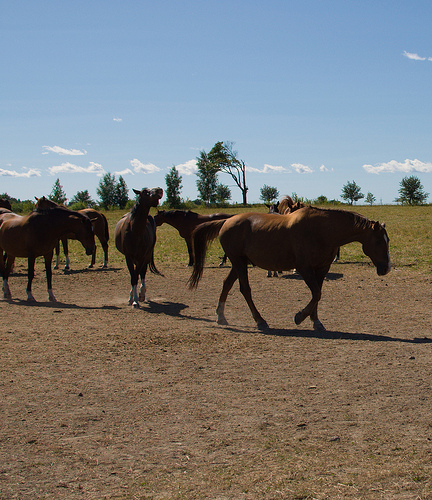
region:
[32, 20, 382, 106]
patch of clear blue sky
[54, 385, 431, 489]
smooth grund for walking on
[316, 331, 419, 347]
horse's shadow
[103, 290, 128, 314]
dust kicked up by horse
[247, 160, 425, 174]
row of white, thin clouds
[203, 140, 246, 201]
tree with no leaves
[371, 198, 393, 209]
fence for boundaries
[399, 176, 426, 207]
short tree with leaves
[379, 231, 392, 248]
white strip of fur on horse's head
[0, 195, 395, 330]
cluster of horses roaming the grounds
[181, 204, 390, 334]
brown horse on a field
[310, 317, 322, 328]
hoove of a horse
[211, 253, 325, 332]
four legs of a horse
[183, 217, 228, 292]
brown tail of a horse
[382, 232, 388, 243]
white spot on a horses head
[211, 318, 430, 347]
horse shadow on a ground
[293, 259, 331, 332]
front legs of a horse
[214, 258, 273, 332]
back legs of a horse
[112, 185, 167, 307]
brown horse with its head in the air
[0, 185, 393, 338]
brown horses on a dirt ground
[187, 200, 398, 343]
brown horse walking on dirt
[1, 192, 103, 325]
brown horse walking on dirt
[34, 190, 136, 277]
brown horse walking on dirt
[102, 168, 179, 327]
brown horse walking on dirt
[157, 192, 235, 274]
brown horse walking on dirt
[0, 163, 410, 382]
brown horses walking on dirt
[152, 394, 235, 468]
area of loose dirt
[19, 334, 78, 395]
area of loose dirt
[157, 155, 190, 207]
tall green leafy tree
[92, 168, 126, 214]
tall green leafy tree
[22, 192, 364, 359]
horses are in field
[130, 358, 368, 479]
ground is dry and brown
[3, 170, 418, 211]
few trees in distance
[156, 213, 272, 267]
horse has brown tail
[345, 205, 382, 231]
horse has brown ears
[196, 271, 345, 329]
white and brown legs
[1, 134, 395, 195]
few narrow clouds in sky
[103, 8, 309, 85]
sky is blue and clear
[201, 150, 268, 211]
bare tree in background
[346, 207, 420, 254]
green grass behind horses